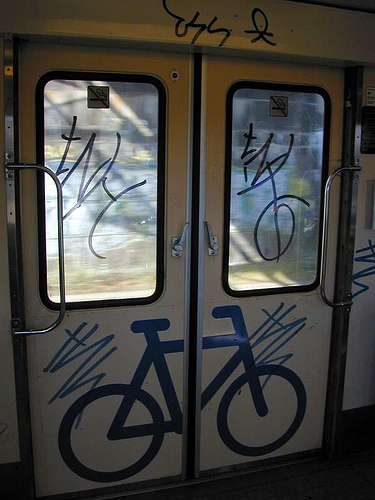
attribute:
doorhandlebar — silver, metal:
[4, 162, 67, 335]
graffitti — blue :
[36, 318, 119, 428]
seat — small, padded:
[124, 311, 189, 334]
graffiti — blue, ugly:
[58, 128, 151, 265]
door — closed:
[16, 39, 331, 450]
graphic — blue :
[55, 306, 305, 482]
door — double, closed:
[10, 36, 353, 498]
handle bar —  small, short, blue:
[211, 304, 243, 319]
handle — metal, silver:
[316, 159, 368, 315]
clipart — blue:
[56, 302, 307, 483]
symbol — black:
[58, 304, 308, 483]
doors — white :
[58, 51, 319, 405]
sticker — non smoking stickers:
[88, 86, 110, 108]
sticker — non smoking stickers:
[270, 95, 287, 116]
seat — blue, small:
[123, 315, 174, 339]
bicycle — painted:
[52, 300, 327, 492]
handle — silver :
[148, 208, 198, 259]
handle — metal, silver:
[317, 163, 364, 318]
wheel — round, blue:
[56, 379, 166, 483]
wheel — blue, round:
[216, 360, 318, 459]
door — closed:
[190, 56, 345, 479]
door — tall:
[16, 40, 198, 499]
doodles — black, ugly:
[56, 115, 147, 258]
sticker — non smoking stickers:
[269, 95, 291, 115]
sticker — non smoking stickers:
[84, 82, 111, 108]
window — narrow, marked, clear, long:
[227, 85, 329, 289]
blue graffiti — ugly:
[40, 322, 126, 429]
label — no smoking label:
[265, 94, 290, 117]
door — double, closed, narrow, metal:
[36, 72, 355, 480]